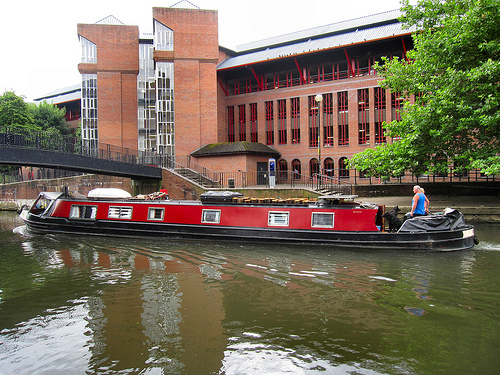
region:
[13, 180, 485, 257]
RED CABIN BOAT ON WATER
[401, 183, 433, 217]
PERSON RIDING ON BOAT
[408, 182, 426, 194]
HEAD OF RIDING PERSON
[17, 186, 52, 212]
CABIN AREA OF BOAT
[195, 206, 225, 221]
WINDOW OF RED BOAT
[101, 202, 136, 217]
WINDOW OF RED BOAT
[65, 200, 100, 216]
WINDOW OF RED BOAT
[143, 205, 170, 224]
WINDOW OF RED BOAT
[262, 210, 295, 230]
WINDOW OF RED BOAT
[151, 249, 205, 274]
PART OF BOAT REFLECTION ON WATER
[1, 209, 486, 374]
water near a building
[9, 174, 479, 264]
boat in the water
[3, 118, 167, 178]
bridge over the water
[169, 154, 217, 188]
steps to the bridge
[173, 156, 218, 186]
rails on the stairs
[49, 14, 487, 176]
building next to water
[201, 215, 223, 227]
window on the boat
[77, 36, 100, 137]
windows on the building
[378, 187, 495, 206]
pavement near the water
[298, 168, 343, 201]
steps near the building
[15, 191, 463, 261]
long boat under bridge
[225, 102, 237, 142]
tall window on parking garage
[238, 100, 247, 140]
tall window on parking garage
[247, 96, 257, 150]
tall window on parking garage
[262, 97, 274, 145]
tall window on parking garage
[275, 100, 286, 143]
tall window on parking garage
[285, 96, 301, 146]
tall window on parking garage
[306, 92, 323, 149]
tall window on parking garage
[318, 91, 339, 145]
tall window on parking garage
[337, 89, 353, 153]
tall window on parking garage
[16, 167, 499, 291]
small red boat traveling in green water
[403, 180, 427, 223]
man wearing bright blue tank top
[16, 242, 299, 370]
reflection of the building and boat in water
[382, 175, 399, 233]
two black dogs riding on the boat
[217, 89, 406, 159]
windows on brick building with red bars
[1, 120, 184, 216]
bridge that goes over the small lake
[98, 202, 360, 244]
framed windows on the red boat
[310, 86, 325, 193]
white light on the black metal post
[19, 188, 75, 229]
front of the boat with open windows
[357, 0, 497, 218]
large green leafy tree near the water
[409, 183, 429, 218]
woman in blue standing on boat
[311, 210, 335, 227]
window in side of boat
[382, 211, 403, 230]
black dog on deck of boat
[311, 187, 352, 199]
stairs to upper level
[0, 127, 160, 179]
bridge spanning over water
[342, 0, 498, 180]
large tree with green leaves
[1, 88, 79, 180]
trees growing next to building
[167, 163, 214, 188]
stairs leading to bridge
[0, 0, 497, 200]
large brick building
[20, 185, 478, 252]
long red houseboat in water